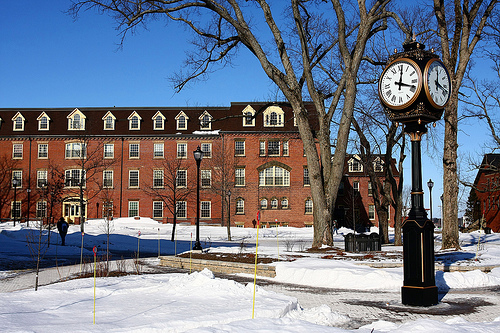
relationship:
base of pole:
[400, 284, 439, 306] [398, 119, 442, 307]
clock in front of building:
[372, 59, 425, 114] [3, 90, 306, 234]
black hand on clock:
[397, 64, 403, 90] [377, 30, 453, 307]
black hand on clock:
[393, 80, 413, 88] [377, 30, 453, 307]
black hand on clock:
[434, 66, 440, 91] [377, 30, 453, 307]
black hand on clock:
[433, 79, 447, 92] [377, 30, 453, 307]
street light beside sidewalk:
[191, 146, 205, 252] [129, 229, 221, 294]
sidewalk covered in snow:
[135, 254, 499, 331] [0, 215, 496, 326]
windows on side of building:
[113, 107, 206, 186] [14, 86, 362, 256]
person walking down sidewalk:
[48, 212, 70, 245] [24, 232, 165, 257]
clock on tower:
[421, 57, 453, 107] [380, 42, 450, 307]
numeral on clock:
[395, 94, 403, 103] [381, 54, 425, 114]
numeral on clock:
[382, 81, 392, 91] [374, 56, 426, 110]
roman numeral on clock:
[381, 72, 396, 80] [380, 55, 417, 110]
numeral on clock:
[408, 63, 418, 79] [375, 48, 445, 132]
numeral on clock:
[409, 70, 416, 77] [380, 57, 423, 107]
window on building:
[129, 139, 144, 156] [0, 107, 332, 225]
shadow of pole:
[83, 297, 263, 322] [378, 28, 450, 303]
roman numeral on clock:
[403, 64, 411, 74] [335, 18, 449, 135]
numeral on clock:
[409, 70, 416, 77] [335, 18, 449, 135]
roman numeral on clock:
[410, 76, 418, 84] [335, 18, 449, 135]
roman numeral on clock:
[388, 90, 398, 102] [335, 18, 449, 135]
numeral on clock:
[382, 83, 392, 90] [335, 18, 449, 135]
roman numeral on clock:
[390, 68, 399, 76] [335, 18, 449, 135]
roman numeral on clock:
[395, 60, 408, 73] [374, 56, 426, 110]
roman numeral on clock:
[403, 63, 411, 73] [374, 56, 426, 110]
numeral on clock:
[409, 70, 416, 77] [374, 56, 426, 110]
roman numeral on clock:
[410, 78, 420, 84] [374, 56, 426, 110]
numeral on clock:
[398, 96, 405, 104] [374, 56, 426, 110]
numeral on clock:
[398, 96, 405, 104] [369, 34, 454, 122]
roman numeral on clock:
[403, 90, 411, 100] [369, 34, 454, 122]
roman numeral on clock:
[407, 81, 417, 91] [369, 34, 454, 122]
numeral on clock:
[409, 70, 416, 77] [369, 34, 454, 122]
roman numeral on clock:
[384, 88, 394, 96] [369, 34, 454, 122]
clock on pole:
[357, 30, 458, 159] [398, 119, 442, 307]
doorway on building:
[63, 197, 85, 223] [41, 55, 397, 326]